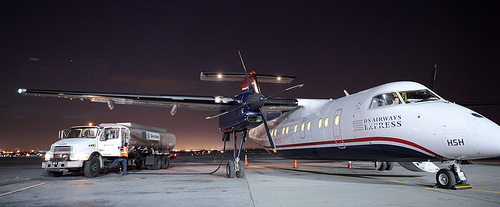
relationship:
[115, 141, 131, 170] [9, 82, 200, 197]
person standing by truck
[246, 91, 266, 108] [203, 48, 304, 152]
core of propeller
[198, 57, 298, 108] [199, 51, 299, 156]
blade of propeller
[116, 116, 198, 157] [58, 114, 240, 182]
tank on a truck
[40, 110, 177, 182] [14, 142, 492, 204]
truck on a tarmac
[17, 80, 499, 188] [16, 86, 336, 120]
plane has wing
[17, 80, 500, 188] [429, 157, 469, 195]
plane has wheel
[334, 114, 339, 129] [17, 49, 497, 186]
window on plane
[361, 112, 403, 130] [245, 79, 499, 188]
airline's name on side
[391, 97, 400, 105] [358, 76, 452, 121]
pilot in cockpit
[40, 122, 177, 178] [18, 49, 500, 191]
truck refueling airplain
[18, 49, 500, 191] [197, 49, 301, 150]
airplain has propeller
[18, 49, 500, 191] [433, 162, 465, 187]
airplain has gear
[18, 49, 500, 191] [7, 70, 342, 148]
airplain has wing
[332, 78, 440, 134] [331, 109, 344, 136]
cabin has closed door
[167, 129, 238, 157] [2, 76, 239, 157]
city has lights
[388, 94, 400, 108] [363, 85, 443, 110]
pilot in cockpit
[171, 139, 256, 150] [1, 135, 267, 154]
glow on horizon